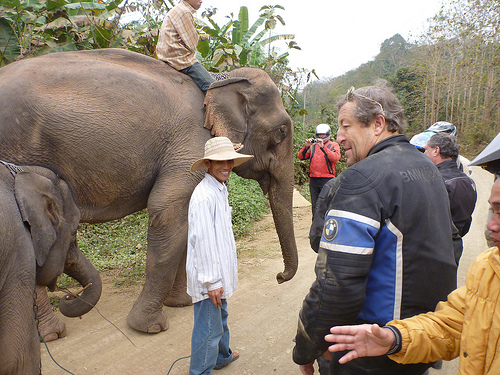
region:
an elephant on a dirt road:
[2, 46, 297, 337]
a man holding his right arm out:
[321, 175, 496, 370]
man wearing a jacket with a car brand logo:
[290, 132, 460, 362]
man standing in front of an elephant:
[0, 46, 295, 371]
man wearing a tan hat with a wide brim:
[186, 135, 251, 172]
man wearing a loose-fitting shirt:
[182, 170, 237, 300]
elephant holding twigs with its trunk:
[2, 163, 139, 374]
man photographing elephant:
[216, 63, 339, 286]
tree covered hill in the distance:
[295, 28, 498, 138]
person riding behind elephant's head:
[154, 1, 296, 183]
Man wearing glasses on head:
[335, 83, 407, 170]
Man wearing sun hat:
[192, 138, 249, 179]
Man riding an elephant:
[157, 0, 223, 90]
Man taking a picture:
[306, 120, 333, 147]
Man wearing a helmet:
[315, 121, 332, 143]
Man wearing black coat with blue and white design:
[327, 86, 425, 316]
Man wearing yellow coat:
[457, 170, 499, 374]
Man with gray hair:
[336, 83, 405, 165]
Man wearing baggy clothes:
[182, 137, 245, 371]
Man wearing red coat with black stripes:
[299, 121, 339, 176]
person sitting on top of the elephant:
[157, 0, 230, 104]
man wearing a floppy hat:
[185, 125, 252, 185]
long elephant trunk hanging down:
[256, 169, 303, 285]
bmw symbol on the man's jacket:
[316, 210, 341, 244]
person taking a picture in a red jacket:
[300, 109, 342, 197]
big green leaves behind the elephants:
[6, 0, 134, 55]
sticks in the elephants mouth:
[57, 282, 159, 342]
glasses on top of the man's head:
[343, 73, 388, 121]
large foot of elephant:
[121, 280, 178, 344]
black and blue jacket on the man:
[271, 148, 463, 366]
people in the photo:
[72, 12, 496, 314]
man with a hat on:
[190, 113, 267, 183]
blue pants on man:
[179, 288, 239, 373]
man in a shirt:
[141, 131, 296, 323]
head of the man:
[310, 85, 428, 173]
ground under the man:
[244, 300, 289, 357]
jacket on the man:
[282, 142, 471, 339]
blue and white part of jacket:
[331, 204, 378, 279]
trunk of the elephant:
[255, 158, 308, 283]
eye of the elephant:
[257, 113, 295, 156]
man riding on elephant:
[151, 3, 231, 90]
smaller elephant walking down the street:
[4, 158, 115, 373]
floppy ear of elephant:
[205, 75, 248, 142]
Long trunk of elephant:
[260, 168, 305, 288]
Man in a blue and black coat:
[315, 88, 447, 334]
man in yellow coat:
[458, 170, 498, 373]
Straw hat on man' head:
[182, 125, 262, 172]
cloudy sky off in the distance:
[316, 18, 375, 50]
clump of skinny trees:
[399, 18, 499, 83]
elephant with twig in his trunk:
[54, 254, 106, 337]